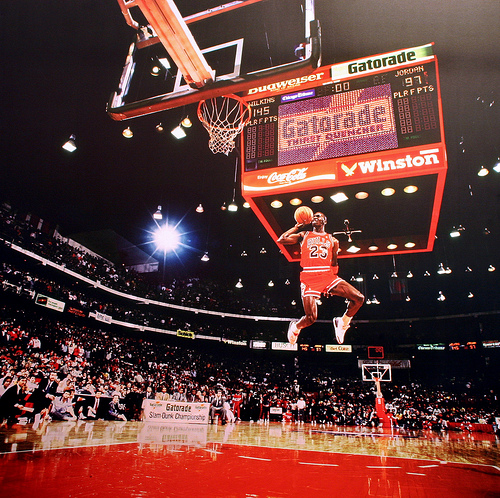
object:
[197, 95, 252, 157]
net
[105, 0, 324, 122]
backboard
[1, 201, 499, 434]
crowd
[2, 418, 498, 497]
court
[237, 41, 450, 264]
jumbo tron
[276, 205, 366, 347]
player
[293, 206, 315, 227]
basketball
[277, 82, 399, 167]
advertisement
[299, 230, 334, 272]
jersey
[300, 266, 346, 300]
shorts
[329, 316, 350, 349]
shoes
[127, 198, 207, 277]
light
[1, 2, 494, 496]
stadium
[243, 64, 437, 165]
scoreboard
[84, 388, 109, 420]
people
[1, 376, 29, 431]
man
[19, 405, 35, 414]
papers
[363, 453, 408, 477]
markings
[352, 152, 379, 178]
letter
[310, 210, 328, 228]
head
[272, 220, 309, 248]
arm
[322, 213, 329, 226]
ear